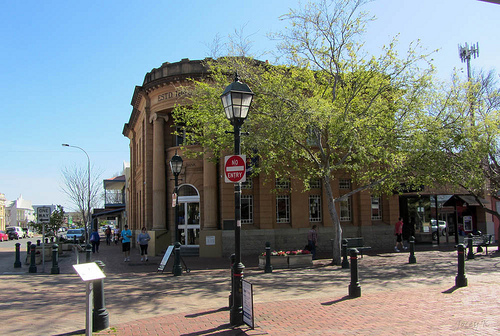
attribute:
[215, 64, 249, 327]
street lamp — black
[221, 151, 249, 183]
sign — red, white, no entry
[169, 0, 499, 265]
tree — leafy, green, large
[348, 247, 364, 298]
post — black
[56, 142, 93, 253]
lightpost — curved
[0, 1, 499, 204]
sky — blue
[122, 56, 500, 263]
building — large, brown, tan, old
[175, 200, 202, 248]
door — white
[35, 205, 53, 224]
sign — one way sign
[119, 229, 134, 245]
shirt — blue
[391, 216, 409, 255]
man — walking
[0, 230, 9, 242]
car — red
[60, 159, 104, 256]
tree — bare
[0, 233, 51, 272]
street — quiet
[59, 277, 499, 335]
pavement — red brick, brick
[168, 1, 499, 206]
leaves — green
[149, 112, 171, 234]
column — roman style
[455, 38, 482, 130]
cellphone tower — tall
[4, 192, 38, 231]
building — white, large